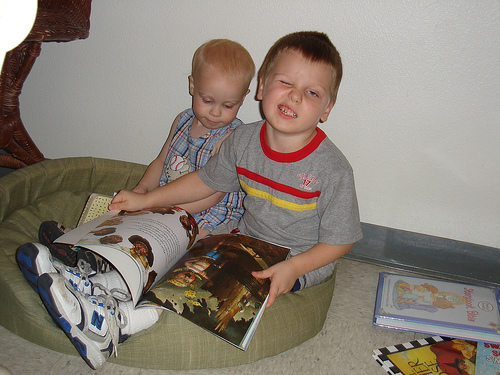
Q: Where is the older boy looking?
A: Camera.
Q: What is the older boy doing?
A: Winking.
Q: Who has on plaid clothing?
A: Younger child.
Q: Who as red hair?
A: Younger child.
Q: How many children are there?
A: Two.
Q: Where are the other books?
A: Floor.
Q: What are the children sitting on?
A: Dog bed.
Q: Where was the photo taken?
A: In a living room.